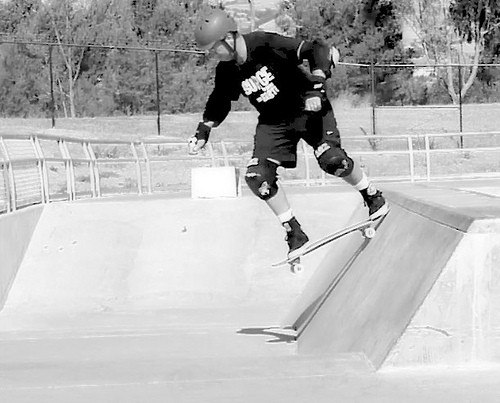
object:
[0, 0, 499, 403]
picture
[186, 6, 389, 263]
man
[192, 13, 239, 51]
helmet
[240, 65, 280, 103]
lettering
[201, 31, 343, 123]
shirt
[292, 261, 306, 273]
gear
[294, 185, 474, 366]
ramp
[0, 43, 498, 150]
fence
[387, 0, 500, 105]
trees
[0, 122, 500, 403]
skate park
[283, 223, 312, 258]
shoes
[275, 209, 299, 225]
socks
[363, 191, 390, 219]
feet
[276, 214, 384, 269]
skateboard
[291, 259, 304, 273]
wheel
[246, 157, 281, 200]
knee pads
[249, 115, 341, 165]
shorts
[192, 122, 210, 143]
glove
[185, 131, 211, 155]
hand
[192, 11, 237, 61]
head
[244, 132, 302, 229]
leg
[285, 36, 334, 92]
arm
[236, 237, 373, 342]
shadow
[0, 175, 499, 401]
ground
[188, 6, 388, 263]
skateboarder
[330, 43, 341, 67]
elbow pad